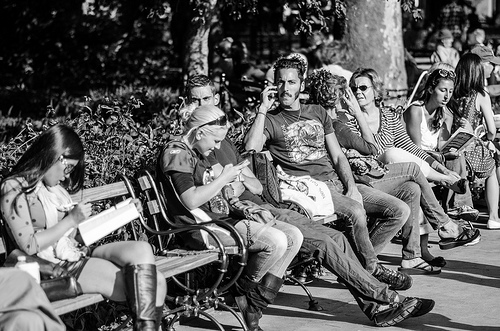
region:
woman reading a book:
[422, 64, 479, 173]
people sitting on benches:
[5, 51, 495, 328]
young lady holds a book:
[7, 116, 174, 329]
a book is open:
[69, 191, 149, 247]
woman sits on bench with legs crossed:
[0, 119, 176, 330]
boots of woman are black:
[116, 254, 173, 329]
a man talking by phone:
[246, 53, 344, 155]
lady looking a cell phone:
[166, 102, 261, 216]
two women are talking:
[307, 61, 414, 155]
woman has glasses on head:
[407, 64, 467, 122]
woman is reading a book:
[411, 56, 485, 168]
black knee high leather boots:
[123, 262, 172, 328]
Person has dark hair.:
[28, 117, 88, 163]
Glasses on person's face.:
[54, 148, 113, 176]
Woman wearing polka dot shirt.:
[8, 178, 38, 222]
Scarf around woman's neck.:
[26, 180, 104, 252]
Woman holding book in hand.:
[80, 192, 163, 254]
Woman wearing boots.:
[110, 267, 190, 317]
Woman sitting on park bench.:
[43, 170, 171, 325]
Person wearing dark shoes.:
[380, 290, 424, 326]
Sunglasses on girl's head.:
[206, 110, 241, 151]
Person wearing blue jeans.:
[319, 234, 369, 283]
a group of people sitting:
[48, 41, 498, 261]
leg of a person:
[318, 225, 418, 300]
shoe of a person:
[367, 295, 407, 327]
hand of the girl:
[61, 193, 105, 225]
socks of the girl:
[126, 262, 171, 326]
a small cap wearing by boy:
[182, 101, 232, 136]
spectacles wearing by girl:
[351, 77, 379, 93]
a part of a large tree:
[306, 0, 426, 96]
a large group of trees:
[44, 21, 498, 121]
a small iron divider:
[133, 177, 245, 287]